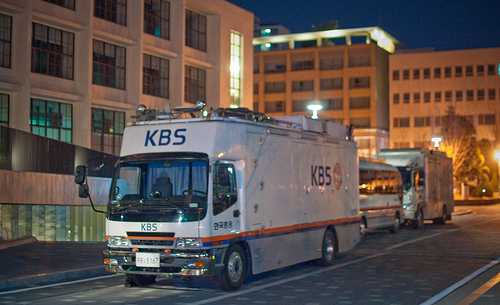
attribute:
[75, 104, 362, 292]
vehicule — large, parked, white, riding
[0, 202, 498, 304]
street — paved, grey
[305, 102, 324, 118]
street light — on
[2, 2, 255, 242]
building — tall, illuminated, multistories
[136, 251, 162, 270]
license plate — white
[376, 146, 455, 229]
truck — large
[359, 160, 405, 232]
bus — large, small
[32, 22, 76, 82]
window — black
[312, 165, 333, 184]
logo — blue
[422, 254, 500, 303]
line — white, painted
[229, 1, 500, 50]
sky — dark